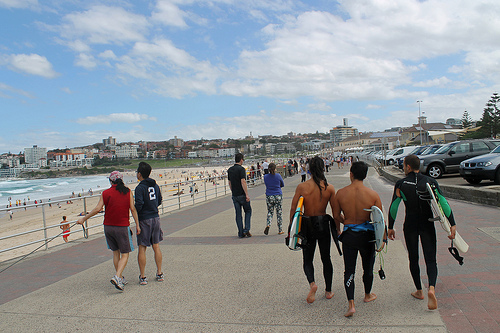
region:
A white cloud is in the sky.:
[238, 14, 400, 106]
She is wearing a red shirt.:
[88, 179, 148, 290]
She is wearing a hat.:
[71, 162, 148, 232]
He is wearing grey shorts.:
[125, 153, 175, 258]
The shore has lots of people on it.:
[5, 140, 81, 247]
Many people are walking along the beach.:
[25, 144, 495, 308]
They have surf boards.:
[285, 146, 472, 312]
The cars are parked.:
[378, 126, 494, 190]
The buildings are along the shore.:
[27, 128, 450, 155]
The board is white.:
[357, 196, 394, 238]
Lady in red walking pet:
[88, 170, 140, 293]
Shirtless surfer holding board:
[291, 146, 328, 318]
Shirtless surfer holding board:
[338, 160, 394, 303]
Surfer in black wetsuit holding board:
[386, 145, 480, 313]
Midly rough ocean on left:
[3, 175, 154, 219]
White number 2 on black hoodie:
[142, 183, 162, 200]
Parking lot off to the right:
[381, 129, 483, 169]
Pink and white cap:
[109, 165, 135, 185]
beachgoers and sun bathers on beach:
[149, 164, 217, 193]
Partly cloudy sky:
[98, 3, 422, 100]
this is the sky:
[33, 80, 105, 112]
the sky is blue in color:
[37, 82, 83, 114]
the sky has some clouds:
[136, 40, 434, 100]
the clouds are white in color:
[298, 39, 351, 81]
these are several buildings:
[29, 132, 410, 158]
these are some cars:
[426, 142, 498, 176]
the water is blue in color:
[11, 180, 48, 192]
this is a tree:
[477, 102, 499, 134]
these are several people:
[91, 147, 473, 316]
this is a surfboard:
[371, 209, 388, 244]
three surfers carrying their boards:
[273, 146, 455, 325]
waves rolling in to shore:
[0, 179, 79, 198]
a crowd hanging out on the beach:
[158, 169, 227, 199]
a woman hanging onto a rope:
[25, 167, 138, 300]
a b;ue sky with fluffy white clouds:
[26, 7, 292, 121]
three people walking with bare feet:
[275, 274, 456, 331]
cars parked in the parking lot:
[409, 131, 499, 191]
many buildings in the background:
[70, 121, 267, 165]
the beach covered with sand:
[13, 217, 44, 232]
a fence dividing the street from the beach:
[168, 175, 230, 204]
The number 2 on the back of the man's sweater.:
[144, 184, 158, 203]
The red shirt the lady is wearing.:
[101, 189, 135, 223]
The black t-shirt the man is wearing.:
[227, 163, 246, 198]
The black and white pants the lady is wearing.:
[260, 195, 285, 221]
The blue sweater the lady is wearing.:
[262, 174, 287, 194]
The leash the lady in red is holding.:
[9, 208, 87, 262]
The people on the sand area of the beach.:
[4, 156, 229, 237]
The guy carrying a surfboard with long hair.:
[294, 144, 353, 267]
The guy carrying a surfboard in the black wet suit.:
[391, 155, 459, 307]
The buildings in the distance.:
[26, 126, 472, 148]